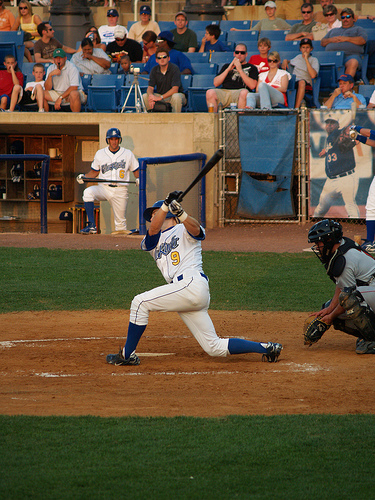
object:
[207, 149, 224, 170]
bat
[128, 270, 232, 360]
pants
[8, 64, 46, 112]
child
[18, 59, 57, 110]
seat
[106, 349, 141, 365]
foot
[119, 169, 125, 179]
number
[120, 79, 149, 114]
stand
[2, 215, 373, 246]
dirt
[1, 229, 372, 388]
field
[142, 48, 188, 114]
guy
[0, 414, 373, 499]
green grass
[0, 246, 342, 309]
green grass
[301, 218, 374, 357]
catcher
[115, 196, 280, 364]
batter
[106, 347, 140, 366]
shoes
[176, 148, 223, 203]
baseball bat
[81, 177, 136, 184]
baseball bat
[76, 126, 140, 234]
man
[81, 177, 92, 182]
bat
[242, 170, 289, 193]
tear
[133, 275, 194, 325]
stripe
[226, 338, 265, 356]
sock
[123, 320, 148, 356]
sock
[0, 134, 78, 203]
storage cubicles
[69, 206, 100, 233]
bat storage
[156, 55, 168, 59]
sunglasses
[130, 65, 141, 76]
camera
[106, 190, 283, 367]
he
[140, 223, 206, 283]
jersey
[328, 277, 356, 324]
arms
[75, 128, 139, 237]
baseball player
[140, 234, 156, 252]
shoulder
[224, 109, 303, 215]
tarp